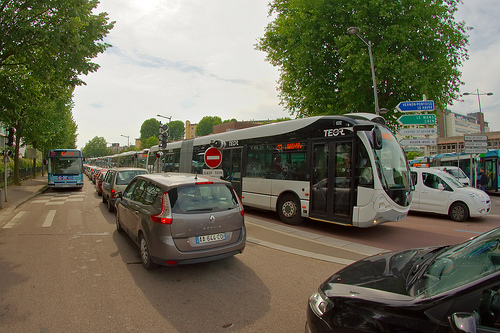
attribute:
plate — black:
[193, 231, 229, 246]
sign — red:
[203, 147, 225, 170]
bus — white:
[149, 115, 411, 229]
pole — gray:
[348, 27, 385, 117]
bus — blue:
[49, 149, 84, 193]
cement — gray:
[242, 213, 379, 261]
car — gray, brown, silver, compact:
[118, 173, 248, 268]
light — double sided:
[153, 122, 174, 166]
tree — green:
[267, 4, 472, 116]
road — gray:
[16, 189, 339, 297]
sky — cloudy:
[87, 9, 281, 118]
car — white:
[403, 167, 491, 224]